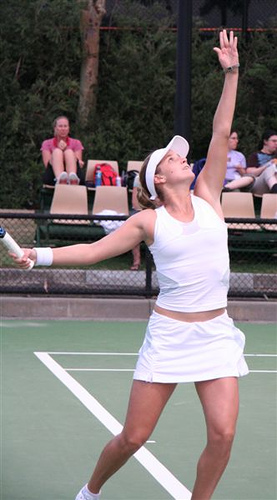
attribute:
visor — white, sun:
[131, 135, 197, 197]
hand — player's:
[212, 28, 239, 69]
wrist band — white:
[33, 246, 53, 268]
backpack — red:
[92, 161, 121, 187]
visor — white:
[142, 134, 191, 202]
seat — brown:
[92, 184, 132, 226]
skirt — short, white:
[141, 311, 243, 383]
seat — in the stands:
[259, 194, 276, 230]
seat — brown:
[53, 184, 90, 222]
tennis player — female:
[6, 28, 249, 498]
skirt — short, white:
[143, 311, 254, 386]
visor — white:
[144, 136, 191, 197]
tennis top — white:
[146, 188, 235, 318]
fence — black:
[1, 208, 275, 297]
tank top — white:
[147, 193, 231, 310]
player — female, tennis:
[17, 28, 247, 497]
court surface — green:
[13, 319, 119, 387]